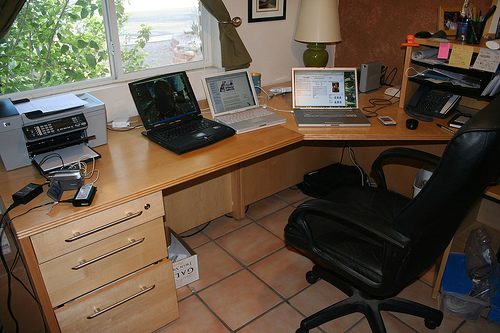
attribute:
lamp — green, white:
[292, 1, 342, 65]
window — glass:
[0, 6, 225, 106]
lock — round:
[141, 202, 156, 212]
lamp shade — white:
[291, 0, 346, 72]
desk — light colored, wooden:
[2, 88, 385, 330]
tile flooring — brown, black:
[125, 184, 498, 330]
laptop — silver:
[285, 62, 375, 137]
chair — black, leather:
[192, 33, 499, 331]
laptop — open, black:
[113, 67, 250, 164]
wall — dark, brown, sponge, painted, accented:
[346, 5, 411, 64]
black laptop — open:
[129, 71, 236, 155]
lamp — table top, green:
[289, 0, 344, 72]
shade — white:
[287, 2, 349, 50]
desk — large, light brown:
[9, 49, 497, 252]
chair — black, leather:
[214, 80, 481, 332]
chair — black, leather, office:
[277, 94, 499, 330]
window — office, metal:
[1, 2, 211, 92]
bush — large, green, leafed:
[13, 55, 111, 91]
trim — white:
[112, 73, 122, 81]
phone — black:
[413, 90, 463, 125]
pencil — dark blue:
[482, 8, 484, 25]